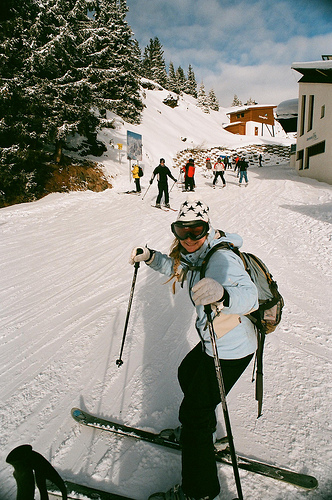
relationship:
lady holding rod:
[126, 200, 263, 499] [115, 247, 143, 366]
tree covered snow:
[0, 19, 95, 154] [9, 256, 91, 379]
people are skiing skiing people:
[150, 157, 250, 212] [146, 155, 252, 204]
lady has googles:
[126, 200, 263, 499] [168, 220, 209, 239]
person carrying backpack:
[130, 163, 144, 190] [135, 165, 144, 176]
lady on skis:
[127, 200, 261, 498] [33, 406, 318, 499]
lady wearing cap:
[127, 200, 261, 498] [177, 199, 212, 226]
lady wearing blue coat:
[127, 200, 261, 498] [122, 223, 264, 368]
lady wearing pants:
[127, 200, 261, 498] [177, 338, 254, 498]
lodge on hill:
[222, 103, 277, 135] [0, 72, 299, 206]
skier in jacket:
[180, 157, 198, 179] [183, 165, 194, 177]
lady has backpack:
[127, 200, 261, 498] [236, 250, 284, 334]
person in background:
[130, 163, 144, 190] [1, 0, 330, 206]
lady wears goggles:
[127, 200, 261, 498] [169, 220, 209, 240]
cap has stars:
[168, 198, 213, 225] [180, 201, 202, 217]